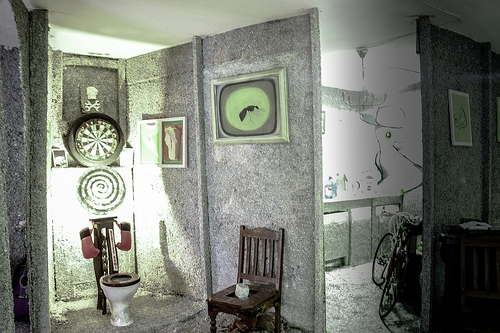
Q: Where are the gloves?
A: On the toilet.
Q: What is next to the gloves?
A: The toilet.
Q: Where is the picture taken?
A: A bathroom.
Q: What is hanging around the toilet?
A: Red stockings.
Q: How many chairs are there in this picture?
A: 2.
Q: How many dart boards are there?
A: 1.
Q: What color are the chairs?
A: Brown.